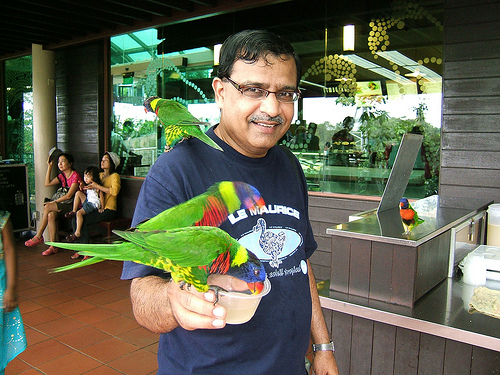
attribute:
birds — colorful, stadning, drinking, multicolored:
[162, 175, 278, 291]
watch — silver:
[315, 337, 339, 356]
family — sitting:
[50, 127, 131, 202]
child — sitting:
[61, 170, 106, 214]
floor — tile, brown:
[35, 293, 118, 363]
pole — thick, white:
[29, 70, 67, 115]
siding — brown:
[454, 34, 483, 120]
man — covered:
[162, 41, 320, 375]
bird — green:
[126, 98, 204, 150]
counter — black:
[348, 208, 385, 242]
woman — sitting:
[95, 145, 120, 209]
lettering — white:
[271, 197, 301, 221]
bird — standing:
[393, 193, 427, 225]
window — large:
[288, 5, 419, 166]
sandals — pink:
[27, 239, 60, 257]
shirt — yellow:
[102, 174, 125, 211]